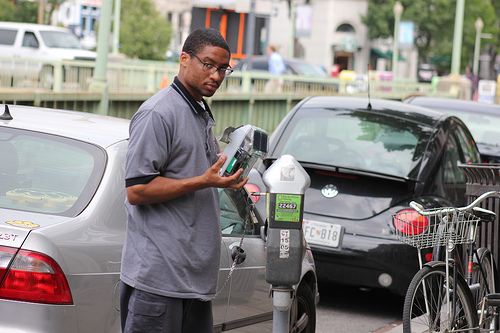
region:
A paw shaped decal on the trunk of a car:
[9, 216, 39, 230]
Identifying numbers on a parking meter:
[275, 195, 301, 212]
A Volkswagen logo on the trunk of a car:
[319, 183, 337, 199]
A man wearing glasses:
[206, 65, 230, 73]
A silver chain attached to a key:
[226, 237, 238, 286]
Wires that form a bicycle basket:
[416, 227, 431, 245]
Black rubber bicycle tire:
[402, 298, 410, 330]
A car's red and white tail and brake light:
[18, 255, 62, 303]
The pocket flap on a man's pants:
[126, 298, 165, 321]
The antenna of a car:
[1, 95, 11, 119]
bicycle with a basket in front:
[391, 188, 498, 331]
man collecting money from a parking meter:
[111, 27, 316, 331]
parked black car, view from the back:
[248, 64, 483, 300]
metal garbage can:
[455, 159, 497, 301]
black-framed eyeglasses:
[188, 52, 233, 79]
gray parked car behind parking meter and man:
[0, 102, 319, 331]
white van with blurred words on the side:
[0, 19, 95, 86]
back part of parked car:
[403, 84, 498, 162]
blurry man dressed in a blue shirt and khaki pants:
[265, 41, 289, 94]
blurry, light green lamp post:
[385, 0, 411, 102]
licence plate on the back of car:
[301, 218, 346, 247]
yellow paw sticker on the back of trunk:
[6, 213, 38, 230]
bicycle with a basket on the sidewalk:
[395, 190, 497, 330]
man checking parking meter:
[125, 56, 261, 328]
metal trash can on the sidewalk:
[455, 158, 498, 229]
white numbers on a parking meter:
[275, 199, 299, 212]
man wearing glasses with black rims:
[185, 47, 237, 79]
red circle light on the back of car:
[393, 205, 427, 241]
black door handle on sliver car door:
[230, 240, 251, 276]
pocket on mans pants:
[125, 297, 172, 331]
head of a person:
[173, 28, 233, 102]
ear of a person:
[179, 43, 196, 71]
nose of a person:
[206, 66, 226, 83]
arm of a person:
[120, 131, 202, 218]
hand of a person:
[205, 145, 250, 200]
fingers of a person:
[216, 141, 250, 192]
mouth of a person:
[199, 83, 224, 91]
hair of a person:
[192, 21, 234, 49]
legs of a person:
[100, 261, 215, 329]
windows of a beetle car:
[276, 81, 443, 182]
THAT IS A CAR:
[1, 115, 131, 320]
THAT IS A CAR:
[275, 97, 481, 244]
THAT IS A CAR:
[234, 45, 335, 80]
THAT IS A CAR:
[1, 20, 91, 86]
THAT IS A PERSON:
[263, 40, 280, 87]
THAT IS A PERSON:
[118, 23, 241, 324]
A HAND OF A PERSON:
[144, 160, 249, 196]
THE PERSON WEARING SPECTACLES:
[199, 57, 239, 79]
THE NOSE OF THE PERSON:
[206, 69, 228, 84]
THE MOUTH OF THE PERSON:
[197, 78, 222, 98]